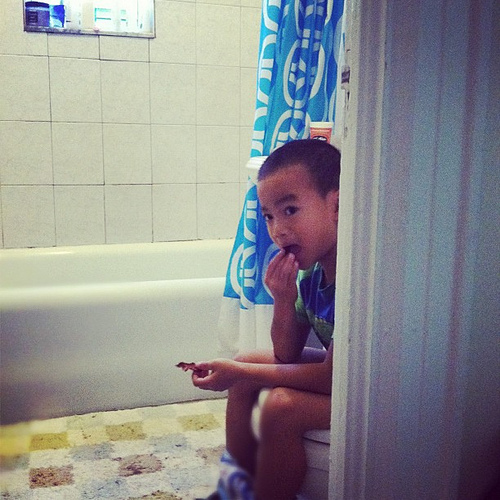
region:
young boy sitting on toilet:
[194, 136, 391, 493]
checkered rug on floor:
[17, 386, 220, 497]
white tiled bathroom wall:
[44, 61, 236, 238]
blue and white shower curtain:
[227, 1, 365, 306]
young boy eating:
[160, 132, 360, 408]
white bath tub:
[12, 203, 242, 413]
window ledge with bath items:
[19, 1, 165, 40]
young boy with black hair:
[224, 123, 355, 276]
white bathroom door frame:
[327, 167, 484, 494]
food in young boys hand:
[178, 351, 220, 389]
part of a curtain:
[255, 67, 299, 117]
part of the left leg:
[277, 448, 301, 480]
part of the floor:
[156, 472, 193, 494]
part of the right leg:
[226, 415, 249, 452]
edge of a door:
[326, 363, 357, 422]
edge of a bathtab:
[135, 282, 170, 302]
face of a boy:
[269, 199, 324, 249]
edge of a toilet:
[306, 431, 333, 463]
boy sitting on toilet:
[190, 137, 340, 498]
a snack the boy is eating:
[177, 361, 198, 373]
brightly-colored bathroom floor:
[0, 395, 228, 498]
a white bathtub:
[0, 236, 240, 423]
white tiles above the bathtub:
[0, 0, 260, 251]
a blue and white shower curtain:
[214, 1, 339, 353]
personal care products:
[25, 1, 131, 36]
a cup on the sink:
[307, 120, 333, 142]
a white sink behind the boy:
[247, 155, 267, 182]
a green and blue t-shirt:
[293, 263, 336, 348]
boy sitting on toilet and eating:
[150, 133, 346, 483]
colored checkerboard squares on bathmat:
[35, 412, 200, 492]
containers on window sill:
[10, 0, 160, 40]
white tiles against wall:
[37, 85, 218, 202]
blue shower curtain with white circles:
[227, 15, 327, 332]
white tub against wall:
[25, 191, 255, 421]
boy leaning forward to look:
[255, 125, 347, 300]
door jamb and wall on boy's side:
[326, 17, 476, 462]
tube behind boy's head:
[295, 97, 335, 152]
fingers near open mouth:
[250, 215, 313, 280]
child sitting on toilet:
[249, 193, 371, 461]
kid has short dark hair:
[249, 155, 335, 227]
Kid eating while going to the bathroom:
[247, 223, 312, 287]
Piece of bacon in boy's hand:
[139, 370, 232, 416]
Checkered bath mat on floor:
[23, 424, 248, 471]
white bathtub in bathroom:
[3, 239, 228, 350]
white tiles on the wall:
[25, 165, 142, 229]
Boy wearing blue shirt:
[288, 279, 355, 351]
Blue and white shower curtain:
[203, 189, 289, 325]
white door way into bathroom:
[308, 195, 414, 423]